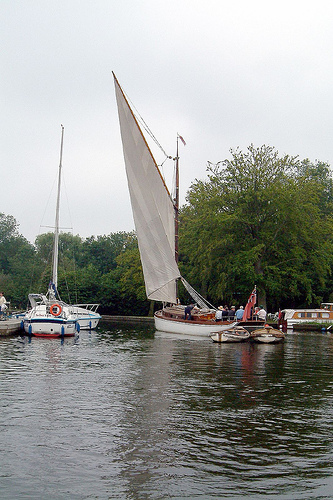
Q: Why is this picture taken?
A: Photography.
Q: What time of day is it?
A: Day time.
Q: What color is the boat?
A: White, wood, blue, red.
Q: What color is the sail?
A: White.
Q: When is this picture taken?
A: While boating.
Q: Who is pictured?
A: Boaters.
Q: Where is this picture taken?
A: Lake.